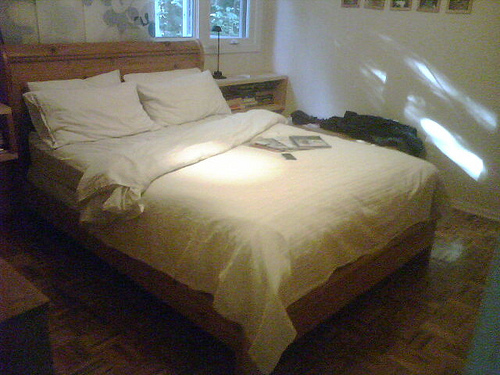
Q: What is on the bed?
A: Magazines.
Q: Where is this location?
A: Bedroom.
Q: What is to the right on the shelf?
A: Lamp.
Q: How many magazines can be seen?
A: Three.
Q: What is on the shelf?
A: Books.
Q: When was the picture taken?
A: Night.